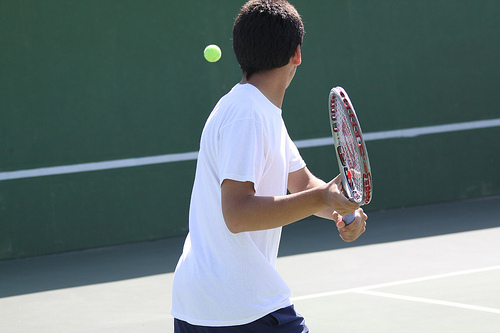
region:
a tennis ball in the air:
[201, 37, 226, 65]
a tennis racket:
[318, 83, 399, 209]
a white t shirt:
[185, 88, 288, 325]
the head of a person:
[231, 1, 309, 82]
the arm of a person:
[223, 163, 313, 238]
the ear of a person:
[293, 39, 307, 67]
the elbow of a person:
[215, 193, 259, 238]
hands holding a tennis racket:
[317, 168, 380, 253]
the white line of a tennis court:
[359, 276, 458, 312]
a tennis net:
[393, 117, 463, 235]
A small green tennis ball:
[200, 43, 227, 70]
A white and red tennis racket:
[312, 86, 372, 218]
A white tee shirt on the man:
[182, 92, 312, 316]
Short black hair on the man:
[228, 5, 302, 89]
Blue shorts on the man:
[171, 292, 313, 329]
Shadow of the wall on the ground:
[365, 206, 490, 243]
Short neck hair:
[236, 70, 268, 92]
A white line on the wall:
[20, 155, 152, 183]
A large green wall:
[17, 26, 179, 131]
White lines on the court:
[372, 250, 454, 331]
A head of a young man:
[234, 0, 313, 80]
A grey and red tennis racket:
[331, 83, 378, 243]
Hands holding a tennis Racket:
[227, 142, 364, 244]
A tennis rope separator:
[16, 151, 200, 179]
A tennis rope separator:
[373, 116, 498, 142]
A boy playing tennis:
[169, 32, 354, 328]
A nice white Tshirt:
[174, 77, 291, 309]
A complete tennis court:
[15, 24, 498, 309]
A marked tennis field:
[312, 259, 489, 320]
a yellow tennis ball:
[187, 32, 235, 77]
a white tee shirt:
[157, 73, 349, 330]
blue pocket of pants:
[263, 285, 302, 332]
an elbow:
[200, 205, 271, 252]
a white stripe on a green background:
[56, 115, 142, 223]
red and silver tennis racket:
[282, 60, 411, 257]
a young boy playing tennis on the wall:
[148, 1, 399, 329]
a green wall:
[33, 39, 121, 136]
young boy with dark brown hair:
[215, 0, 339, 90]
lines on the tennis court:
[362, 266, 449, 331]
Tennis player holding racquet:
[166, 3, 376, 331]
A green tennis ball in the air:
[173, 18, 236, 75]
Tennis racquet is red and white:
[329, 78, 380, 218]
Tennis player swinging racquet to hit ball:
[170, 4, 372, 331]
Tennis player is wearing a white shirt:
[167, 5, 377, 330]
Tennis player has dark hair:
[191, 1, 363, 328]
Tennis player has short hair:
[166, 0, 372, 332]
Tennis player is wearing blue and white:
[172, 4, 372, 329]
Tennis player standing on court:
[137, 3, 437, 330]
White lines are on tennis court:
[304, 262, 498, 331]